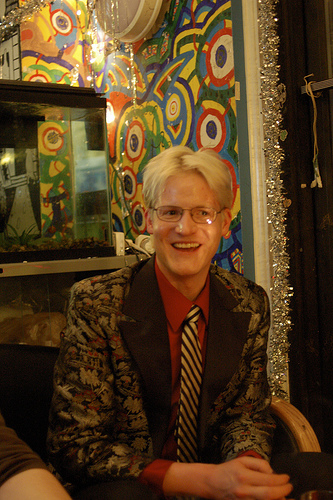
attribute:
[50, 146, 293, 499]
man — smiling, old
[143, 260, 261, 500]
shirt — red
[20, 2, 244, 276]
wall — colorful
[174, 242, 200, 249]
teeth — white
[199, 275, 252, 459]
lapel — large